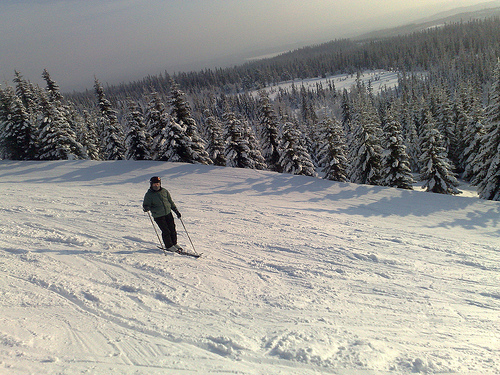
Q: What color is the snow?
A: White.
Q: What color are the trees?
A: Green.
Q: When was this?
A: Daytime.